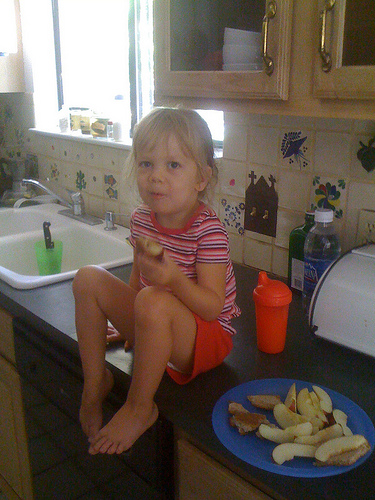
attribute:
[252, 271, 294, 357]
cup — red, orange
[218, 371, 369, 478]
plate — white, blue, filled, close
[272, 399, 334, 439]
apples — red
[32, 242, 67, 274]
cup — green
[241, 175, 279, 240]
light — brown, white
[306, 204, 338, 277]
bottle — clear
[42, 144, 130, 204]
tile — pretty